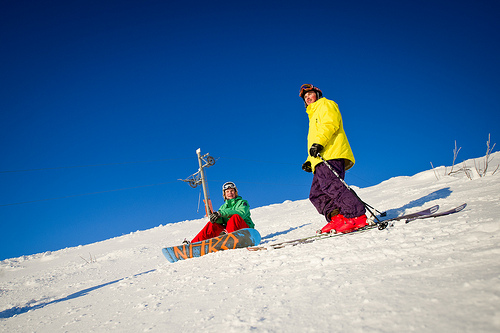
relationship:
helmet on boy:
[222, 180, 239, 200] [182, 182, 255, 243]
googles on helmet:
[221, 182, 236, 189] [222, 180, 239, 200]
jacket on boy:
[218, 197, 253, 228] [182, 182, 255, 243]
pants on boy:
[192, 215, 249, 244] [182, 182, 255, 243]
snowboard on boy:
[163, 228, 261, 263] [182, 182, 255, 243]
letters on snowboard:
[173, 234, 239, 263] [163, 228, 261, 263]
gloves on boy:
[207, 209, 222, 224] [182, 182, 255, 243]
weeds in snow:
[83, 250, 97, 265] [4, 263, 499, 332]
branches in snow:
[448, 132, 499, 180] [4, 263, 499, 332]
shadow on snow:
[375, 186, 453, 219] [4, 263, 499, 332]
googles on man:
[299, 84, 313, 100] [299, 75, 367, 234]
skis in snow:
[245, 204, 468, 253] [4, 263, 499, 332]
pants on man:
[309, 159, 366, 215] [299, 75, 367, 234]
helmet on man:
[315, 87, 322, 101] [299, 75, 367, 234]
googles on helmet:
[299, 84, 313, 100] [315, 87, 322, 101]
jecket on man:
[308, 98, 355, 170] [299, 75, 367, 234]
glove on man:
[310, 144, 321, 157] [299, 75, 367, 234]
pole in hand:
[316, 153, 380, 223] [310, 144, 321, 157]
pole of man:
[365, 202, 387, 219] [299, 75, 367, 234]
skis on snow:
[245, 204, 468, 253] [4, 263, 499, 332]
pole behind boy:
[193, 147, 213, 217] [182, 182, 255, 243]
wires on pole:
[1, 180, 177, 207] [316, 153, 380, 223]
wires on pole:
[219, 157, 302, 168] [193, 147, 213, 217]